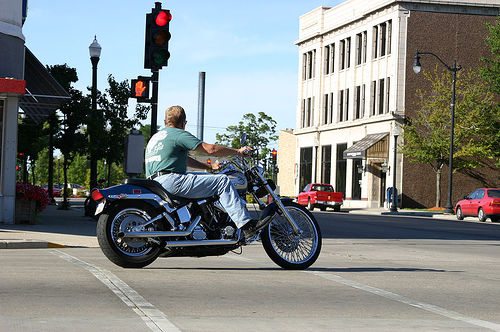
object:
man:
[145, 105, 274, 234]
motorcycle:
[88, 133, 323, 271]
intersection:
[125, 266, 482, 330]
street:
[357, 219, 447, 277]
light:
[148, 11, 174, 28]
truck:
[295, 183, 343, 211]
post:
[87, 35, 103, 214]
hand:
[237, 146, 251, 157]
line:
[100, 268, 166, 316]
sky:
[179, 16, 247, 66]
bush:
[18, 187, 49, 198]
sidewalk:
[44, 200, 92, 235]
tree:
[56, 88, 93, 206]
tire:
[259, 202, 322, 271]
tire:
[96, 198, 166, 269]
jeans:
[146, 171, 253, 230]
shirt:
[144, 127, 203, 178]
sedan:
[455, 188, 499, 222]